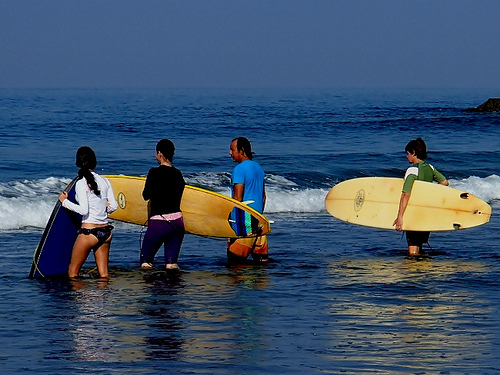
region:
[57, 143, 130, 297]
Woman with a pony tail standing in water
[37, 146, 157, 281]
Woman holding a surf board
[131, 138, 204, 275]
Person standing in water with a black shirt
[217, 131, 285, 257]
Man with a blue shirt standing in water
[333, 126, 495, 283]
Man with a green shirt standing in water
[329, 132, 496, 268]
Man with a green shirt holding a surf board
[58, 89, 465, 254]
People standing in the ocean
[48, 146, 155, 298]
Woman wearing bikini bottoms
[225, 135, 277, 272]
Man wearing yellow and orange shorts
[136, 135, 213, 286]
Woman wearing blue shorts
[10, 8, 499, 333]
Picture is taken during the daytime.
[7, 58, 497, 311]
Picture is taken of the ocean.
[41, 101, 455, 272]
There are four people in the picture.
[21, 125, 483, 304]
Three people are holding surf boards.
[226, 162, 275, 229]
One man is wearing a blue short sleeved shirt.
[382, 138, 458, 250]
One boy is wearing a green and white shirt.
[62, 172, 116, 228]
One woman is wearing a white long sleeved shirt.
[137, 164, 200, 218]
One woman is wearing a black shirt.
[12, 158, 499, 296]
The surfers are walking into the water.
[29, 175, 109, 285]
One woman's surfboard is blue.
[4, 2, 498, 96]
the ocean is blue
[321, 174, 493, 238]
the surfboard is faded and yellow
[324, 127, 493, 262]
the boy is carrying a surfboard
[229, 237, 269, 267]
the man has striped shorts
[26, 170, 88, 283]
the girl has a blue and black boogie board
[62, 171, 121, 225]
the girl is wearing a white long sleeved shirt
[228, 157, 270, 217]
the man is wearing a blue shirt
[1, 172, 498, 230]
the wave is very small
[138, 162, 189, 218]
the woman is wearing a black shirt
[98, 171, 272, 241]
the surfboard is yellow with a striped logo on the tail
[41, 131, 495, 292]
Four people in the sea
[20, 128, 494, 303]
Tree persons carrying surfboards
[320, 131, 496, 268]
Man carrying surfboard under arm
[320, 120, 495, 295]
Man has green shirt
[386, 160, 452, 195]
Shirt has white stripes on sleeves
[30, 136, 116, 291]
Girl with a blue surfboard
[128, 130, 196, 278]
Woman wearing black short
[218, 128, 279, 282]
Man wearing blue shirt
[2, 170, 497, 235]
Weave rolling in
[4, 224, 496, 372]
waters are calm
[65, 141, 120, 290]
woman in a white shirt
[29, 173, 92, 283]
blue surf board in water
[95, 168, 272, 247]
yellow surf board being carried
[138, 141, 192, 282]
woman in black shirt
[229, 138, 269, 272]
man in blue shirt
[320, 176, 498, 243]
white surf board being carried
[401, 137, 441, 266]
male in green and white shirt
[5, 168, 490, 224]
ocean wave rolling in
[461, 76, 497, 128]
rock area in ocean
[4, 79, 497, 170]
blue waters of the ocean